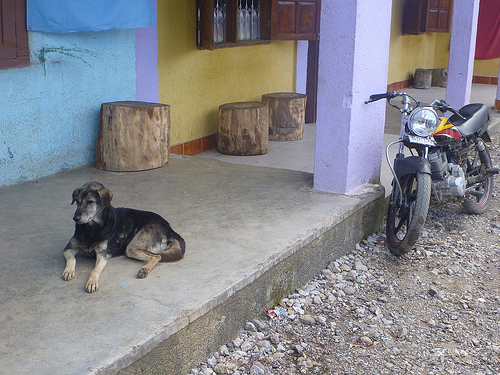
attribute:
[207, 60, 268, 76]
wall — yellow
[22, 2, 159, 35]
curtain — blue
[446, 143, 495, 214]
tire — black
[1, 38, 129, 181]
wall — blue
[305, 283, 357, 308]
rocks — gray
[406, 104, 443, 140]
light — off 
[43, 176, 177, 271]
dog — black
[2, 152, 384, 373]
porch — concrete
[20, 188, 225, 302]
dog — black, tan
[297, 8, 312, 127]
door — open